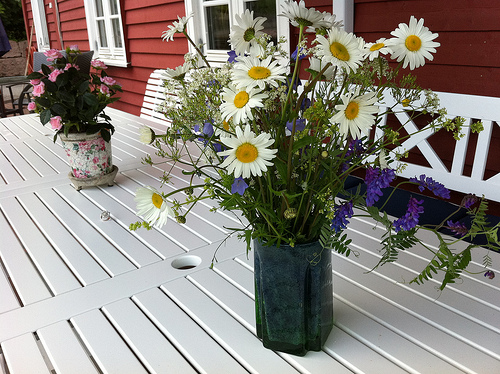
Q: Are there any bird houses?
A: No, there are no bird houses.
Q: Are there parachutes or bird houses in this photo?
A: No, there are no bird houses or parachutes.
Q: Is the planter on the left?
A: Yes, the planter is on the left of the image.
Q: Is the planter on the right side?
A: No, the planter is on the left of the image.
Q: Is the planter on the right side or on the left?
A: The planter is on the left of the image.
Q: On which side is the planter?
A: The planter is on the left of the image.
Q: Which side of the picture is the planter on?
A: The planter is on the left of the image.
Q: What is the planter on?
A: The planter is on the table.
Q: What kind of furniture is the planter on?
A: The planter is on the table.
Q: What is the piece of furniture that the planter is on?
A: The piece of furniture is a table.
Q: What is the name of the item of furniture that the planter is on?
A: The piece of furniture is a table.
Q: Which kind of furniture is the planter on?
A: The planter is on the table.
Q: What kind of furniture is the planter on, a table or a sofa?
A: The planter is on a table.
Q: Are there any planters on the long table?
A: Yes, there is a planter on the table.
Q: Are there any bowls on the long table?
A: No, there is a planter on the table.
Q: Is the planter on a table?
A: Yes, the planter is on a table.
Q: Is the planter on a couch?
A: No, the planter is on a table.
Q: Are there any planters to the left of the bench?
A: Yes, there is a planter to the left of the bench.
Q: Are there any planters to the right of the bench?
A: No, the planter is to the left of the bench.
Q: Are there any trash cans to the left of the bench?
A: No, there is a planter to the left of the bench.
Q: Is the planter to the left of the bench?
A: Yes, the planter is to the left of the bench.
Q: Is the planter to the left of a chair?
A: No, the planter is to the left of the bench.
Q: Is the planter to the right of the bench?
A: No, the planter is to the left of the bench.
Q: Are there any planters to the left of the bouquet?
A: Yes, there is a planter to the left of the bouquet.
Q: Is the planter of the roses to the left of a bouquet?
A: Yes, the planter is to the left of a bouquet.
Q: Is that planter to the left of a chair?
A: No, the planter is to the left of a bouquet.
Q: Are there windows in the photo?
A: Yes, there is a window.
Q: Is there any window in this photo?
A: Yes, there is a window.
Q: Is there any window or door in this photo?
A: Yes, there is a window.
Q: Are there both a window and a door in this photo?
A: No, there is a window but no doors.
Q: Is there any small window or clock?
A: Yes, there is a small window.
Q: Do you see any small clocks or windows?
A: Yes, there is a small window.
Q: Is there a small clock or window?
A: Yes, there is a small window.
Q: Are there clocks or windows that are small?
A: Yes, the window is small.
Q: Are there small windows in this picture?
A: Yes, there is a small window.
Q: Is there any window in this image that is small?
A: Yes, there is a window that is small.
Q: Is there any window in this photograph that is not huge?
A: Yes, there is a small window.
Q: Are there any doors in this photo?
A: No, there are no doors.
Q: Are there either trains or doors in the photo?
A: No, there are no doors or trains.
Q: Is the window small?
A: Yes, the window is small.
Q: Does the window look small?
A: Yes, the window is small.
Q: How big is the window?
A: The window is small.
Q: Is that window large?
A: No, the window is small.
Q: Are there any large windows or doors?
A: No, there is a window but it is small.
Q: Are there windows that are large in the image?
A: No, there is a window but it is small.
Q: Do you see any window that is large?
A: No, there is a window but it is small.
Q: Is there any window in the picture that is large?
A: No, there is a window but it is small.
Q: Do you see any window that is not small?
A: No, there is a window but it is small.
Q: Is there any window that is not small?
A: No, there is a window but it is small.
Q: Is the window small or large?
A: The window is small.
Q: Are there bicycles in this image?
A: No, there are no bicycles.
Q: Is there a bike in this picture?
A: No, there are no bikes.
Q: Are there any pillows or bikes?
A: No, there are no bikes or pillows.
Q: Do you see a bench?
A: Yes, there is a bench.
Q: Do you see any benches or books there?
A: Yes, there is a bench.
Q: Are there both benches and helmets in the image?
A: No, there is a bench but no helmets.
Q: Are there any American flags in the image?
A: No, there are no American flags.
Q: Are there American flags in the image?
A: No, there are no American flags.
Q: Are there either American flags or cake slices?
A: No, there are no American flags or cake slices.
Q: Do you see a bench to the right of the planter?
A: Yes, there is a bench to the right of the planter.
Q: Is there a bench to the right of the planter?
A: Yes, there is a bench to the right of the planter.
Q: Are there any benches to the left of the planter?
A: No, the bench is to the right of the planter.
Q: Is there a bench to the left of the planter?
A: No, the bench is to the right of the planter.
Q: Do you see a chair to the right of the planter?
A: No, there is a bench to the right of the planter.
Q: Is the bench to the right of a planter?
A: Yes, the bench is to the right of a planter.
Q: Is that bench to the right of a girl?
A: No, the bench is to the right of a planter.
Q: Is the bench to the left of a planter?
A: No, the bench is to the right of a planter.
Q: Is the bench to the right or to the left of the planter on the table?
A: The bench is to the right of the planter.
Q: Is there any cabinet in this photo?
A: No, there are no cabinets.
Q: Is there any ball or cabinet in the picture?
A: No, there are no cabinets or balls.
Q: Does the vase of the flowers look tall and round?
A: Yes, the vase is tall and round.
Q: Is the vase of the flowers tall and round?
A: Yes, the vase is tall and round.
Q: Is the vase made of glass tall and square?
A: No, the vase is tall but round.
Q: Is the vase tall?
A: Yes, the vase is tall.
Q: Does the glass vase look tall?
A: Yes, the vase is tall.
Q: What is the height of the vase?
A: The vase is tall.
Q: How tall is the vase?
A: The vase is tall.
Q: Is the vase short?
A: No, the vase is tall.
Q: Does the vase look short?
A: No, the vase is tall.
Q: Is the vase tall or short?
A: The vase is tall.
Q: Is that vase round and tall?
A: Yes, the vase is round and tall.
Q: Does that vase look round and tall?
A: Yes, the vase is round and tall.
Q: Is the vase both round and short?
A: No, the vase is round but tall.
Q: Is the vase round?
A: Yes, the vase is round.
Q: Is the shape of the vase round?
A: Yes, the vase is round.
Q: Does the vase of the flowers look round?
A: Yes, the vase is round.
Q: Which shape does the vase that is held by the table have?
A: The vase has round shape.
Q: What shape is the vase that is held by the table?
A: The vase is round.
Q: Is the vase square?
A: No, the vase is round.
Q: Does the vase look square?
A: No, the vase is round.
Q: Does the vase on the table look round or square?
A: The vase is round.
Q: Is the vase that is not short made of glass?
A: Yes, the vase is made of glass.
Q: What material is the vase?
A: The vase is made of glass.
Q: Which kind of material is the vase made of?
A: The vase is made of glass.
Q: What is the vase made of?
A: The vase is made of glass.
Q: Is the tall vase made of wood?
A: No, the vase is made of glass.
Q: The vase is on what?
A: The vase is on the table.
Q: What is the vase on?
A: The vase is on the table.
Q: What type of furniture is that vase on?
A: The vase is on the table.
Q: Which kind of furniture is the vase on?
A: The vase is on the table.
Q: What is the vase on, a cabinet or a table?
A: The vase is on a table.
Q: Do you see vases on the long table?
A: Yes, there is a vase on the table.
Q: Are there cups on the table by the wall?
A: No, there is a vase on the table.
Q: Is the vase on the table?
A: Yes, the vase is on the table.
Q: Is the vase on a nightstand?
A: No, the vase is on the table.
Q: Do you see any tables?
A: Yes, there is a table.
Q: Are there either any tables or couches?
A: Yes, there is a table.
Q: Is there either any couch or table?
A: Yes, there is a table.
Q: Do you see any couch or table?
A: Yes, there is a table.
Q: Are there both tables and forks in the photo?
A: No, there is a table but no forks.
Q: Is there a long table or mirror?
A: Yes, there is a long table.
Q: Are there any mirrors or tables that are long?
A: Yes, the table is long.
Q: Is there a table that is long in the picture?
A: Yes, there is a long table.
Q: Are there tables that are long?
A: Yes, there is a table that is long.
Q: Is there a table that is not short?
A: Yes, there is a long table.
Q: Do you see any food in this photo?
A: No, there is no food.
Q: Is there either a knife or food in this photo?
A: No, there are no food or knives.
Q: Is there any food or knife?
A: No, there are no food or knives.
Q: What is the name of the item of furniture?
A: The piece of furniture is a table.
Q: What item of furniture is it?
A: The piece of furniture is a table.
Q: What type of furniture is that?
A: This is a table.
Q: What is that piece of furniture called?
A: This is a table.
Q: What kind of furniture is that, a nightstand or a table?
A: This is a table.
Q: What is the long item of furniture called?
A: The piece of furniture is a table.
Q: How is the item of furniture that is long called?
A: The piece of furniture is a table.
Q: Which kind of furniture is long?
A: The furniture is a table.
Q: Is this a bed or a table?
A: This is a table.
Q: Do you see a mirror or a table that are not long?
A: No, there is a table but it is long.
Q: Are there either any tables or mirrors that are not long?
A: No, there is a table but it is long.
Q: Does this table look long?
A: Yes, the table is long.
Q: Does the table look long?
A: Yes, the table is long.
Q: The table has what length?
A: The table is long.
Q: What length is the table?
A: The table is long.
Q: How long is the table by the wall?
A: The table is long.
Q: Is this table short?
A: No, the table is long.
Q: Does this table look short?
A: No, the table is long.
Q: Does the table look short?
A: No, the table is long.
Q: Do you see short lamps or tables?
A: No, there is a table but it is long.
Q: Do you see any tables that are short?
A: No, there is a table but it is long.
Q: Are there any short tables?
A: No, there is a table but it is long.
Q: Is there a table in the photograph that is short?
A: No, there is a table but it is long.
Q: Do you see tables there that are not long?
A: No, there is a table but it is long.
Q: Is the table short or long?
A: The table is long.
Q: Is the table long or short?
A: The table is long.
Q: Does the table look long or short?
A: The table is long.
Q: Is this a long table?
A: Yes, this is a long table.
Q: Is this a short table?
A: No, this is a long table.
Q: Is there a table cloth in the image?
A: No, there are no tablecloths.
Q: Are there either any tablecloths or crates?
A: No, there are no tablecloths or crates.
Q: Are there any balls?
A: No, there are no balls.